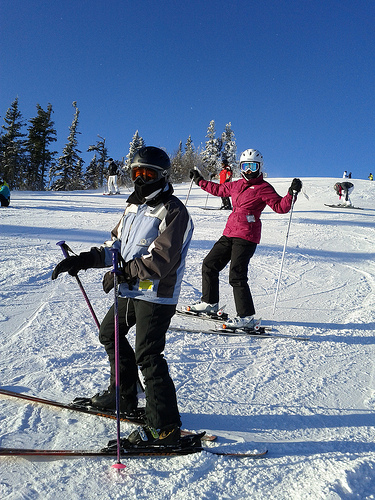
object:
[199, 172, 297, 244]
coat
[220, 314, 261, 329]
boots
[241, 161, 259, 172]
goggles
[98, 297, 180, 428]
pants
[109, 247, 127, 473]
pole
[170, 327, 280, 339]
black skis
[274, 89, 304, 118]
ground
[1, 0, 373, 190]
sky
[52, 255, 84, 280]
glove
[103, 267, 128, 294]
glove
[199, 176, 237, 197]
arm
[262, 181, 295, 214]
arm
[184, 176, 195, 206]
ski pole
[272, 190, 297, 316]
ski pole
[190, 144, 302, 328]
woman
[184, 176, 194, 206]
poles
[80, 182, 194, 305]
coat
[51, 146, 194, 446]
man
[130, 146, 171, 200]
helmet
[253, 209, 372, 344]
ski tracks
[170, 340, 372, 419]
ski tracks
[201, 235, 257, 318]
pants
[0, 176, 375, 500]
snow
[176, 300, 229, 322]
skis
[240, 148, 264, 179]
helmet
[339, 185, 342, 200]
scarf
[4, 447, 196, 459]
writing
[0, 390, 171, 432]
writing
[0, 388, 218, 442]
ski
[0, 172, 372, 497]
ground